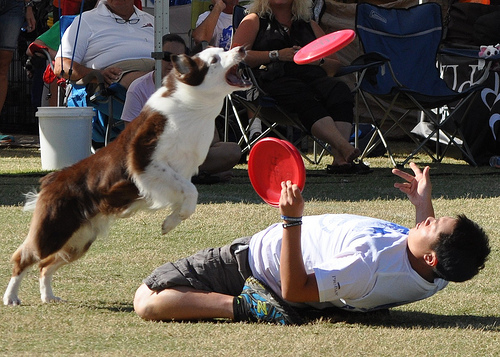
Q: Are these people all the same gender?
A: No, they are both male and female.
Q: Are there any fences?
A: No, there are no fences.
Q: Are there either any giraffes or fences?
A: No, there are no fences or giraffes.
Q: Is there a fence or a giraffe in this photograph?
A: No, there are no fences or giraffes.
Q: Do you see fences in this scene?
A: No, there are no fences.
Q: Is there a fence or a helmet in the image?
A: No, there are no fences or helmets.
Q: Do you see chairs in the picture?
A: Yes, there is a chair.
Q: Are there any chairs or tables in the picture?
A: Yes, there is a chair.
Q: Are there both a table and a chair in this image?
A: No, there is a chair but no tables.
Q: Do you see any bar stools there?
A: No, there are no bar stools.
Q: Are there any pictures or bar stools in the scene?
A: No, there are no bar stools or pictures.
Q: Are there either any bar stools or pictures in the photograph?
A: No, there are no bar stools or pictures.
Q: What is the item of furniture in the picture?
A: The piece of furniture is a chair.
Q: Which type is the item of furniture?
A: The piece of furniture is a chair.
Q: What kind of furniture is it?
A: The piece of furniture is a chair.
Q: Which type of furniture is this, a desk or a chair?
A: That is a chair.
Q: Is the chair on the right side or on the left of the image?
A: The chair is on the right of the image.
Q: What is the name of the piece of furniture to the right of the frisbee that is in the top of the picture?
A: The piece of furniture is a chair.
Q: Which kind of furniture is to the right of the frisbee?
A: The piece of furniture is a chair.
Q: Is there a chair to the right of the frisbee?
A: Yes, there is a chair to the right of the frisbee.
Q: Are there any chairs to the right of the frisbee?
A: Yes, there is a chair to the right of the frisbee.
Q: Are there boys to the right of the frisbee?
A: No, there is a chair to the right of the frisbee.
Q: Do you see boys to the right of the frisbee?
A: No, there is a chair to the right of the frisbee.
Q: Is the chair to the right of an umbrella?
A: No, the chair is to the right of a frisbee.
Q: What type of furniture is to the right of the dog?
A: The piece of furniture is a chair.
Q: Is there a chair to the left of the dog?
A: No, the chair is to the right of the dog.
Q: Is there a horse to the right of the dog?
A: No, there is a chair to the right of the dog.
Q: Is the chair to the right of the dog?
A: Yes, the chair is to the right of the dog.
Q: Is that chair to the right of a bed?
A: No, the chair is to the right of the dog.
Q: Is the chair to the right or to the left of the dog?
A: The chair is to the right of the dog.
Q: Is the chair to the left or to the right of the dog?
A: The chair is to the right of the dog.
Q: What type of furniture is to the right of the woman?
A: The piece of furniture is a chair.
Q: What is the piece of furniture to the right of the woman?
A: The piece of furniture is a chair.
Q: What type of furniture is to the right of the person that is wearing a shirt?
A: The piece of furniture is a chair.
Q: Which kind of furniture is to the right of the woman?
A: The piece of furniture is a chair.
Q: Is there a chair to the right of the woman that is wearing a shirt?
A: Yes, there is a chair to the right of the woman.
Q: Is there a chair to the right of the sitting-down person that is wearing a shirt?
A: Yes, there is a chair to the right of the woman.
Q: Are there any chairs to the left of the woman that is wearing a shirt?
A: No, the chair is to the right of the woman.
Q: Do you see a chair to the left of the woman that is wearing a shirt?
A: No, the chair is to the right of the woman.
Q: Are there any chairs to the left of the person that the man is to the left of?
A: No, the chair is to the right of the woman.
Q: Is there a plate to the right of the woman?
A: No, there is a chair to the right of the woman.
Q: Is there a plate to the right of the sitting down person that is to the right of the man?
A: No, there is a chair to the right of the woman.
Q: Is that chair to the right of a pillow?
A: No, the chair is to the right of the woman.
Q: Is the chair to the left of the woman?
A: No, the chair is to the right of the woman.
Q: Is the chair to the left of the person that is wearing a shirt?
A: No, the chair is to the right of the woman.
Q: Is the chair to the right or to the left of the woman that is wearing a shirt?
A: The chair is to the right of the woman.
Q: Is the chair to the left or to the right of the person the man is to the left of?
A: The chair is to the right of the woman.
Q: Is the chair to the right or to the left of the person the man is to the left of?
A: The chair is to the right of the woman.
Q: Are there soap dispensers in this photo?
A: No, there are no soap dispensers.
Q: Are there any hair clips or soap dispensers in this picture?
A: No, there are no soap dispensers or hair clips.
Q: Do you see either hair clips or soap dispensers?
A: No, there are no soap dispensers or hair clips.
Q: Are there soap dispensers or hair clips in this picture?
A: No, there are no soap dispensers or hair clips.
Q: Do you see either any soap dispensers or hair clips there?
A: No, there are no soap dispensers or hair clips.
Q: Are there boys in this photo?
A: No, there are no boys.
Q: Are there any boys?
A: No, there are no boys.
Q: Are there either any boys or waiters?
A: No, there are no boys or waiters.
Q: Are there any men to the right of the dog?
A: Yes, there is a man to the right of the dog.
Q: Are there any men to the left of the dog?
A: No, the man is to the right of the dog.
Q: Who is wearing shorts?
A: The man is wearing shorts.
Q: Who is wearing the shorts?
A: The man is wearing shorts.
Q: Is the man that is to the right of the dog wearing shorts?
A: Yes, the man is wearing shorts.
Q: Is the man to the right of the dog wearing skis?
A: No, the man is wearing shorts.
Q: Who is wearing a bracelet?
A: The man is wearing a bracelet.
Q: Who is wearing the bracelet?
A: The man is wearing a bracelet.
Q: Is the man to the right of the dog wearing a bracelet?
A: Yes, the man is wearing a bracelet.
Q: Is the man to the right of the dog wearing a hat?
A: No, the man is wearing a bracelet.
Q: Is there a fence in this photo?
A: No, there are no fences.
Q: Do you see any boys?
A: No, there are no boys.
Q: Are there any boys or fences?
A: No, there are no boys or fences.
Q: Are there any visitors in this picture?
A: No, there are no visitors.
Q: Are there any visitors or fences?
A: No, there are no visitors or fences.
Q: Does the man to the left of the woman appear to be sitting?
A: Yes, the man is sitting.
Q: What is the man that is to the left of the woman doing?
A: The man is sitting.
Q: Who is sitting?
A: The man is sitting.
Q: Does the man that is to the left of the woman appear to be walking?
A: No, the man is sitting.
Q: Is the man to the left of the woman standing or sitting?
A: The man is sitting.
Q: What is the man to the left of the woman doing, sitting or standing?
A: The man is sitting.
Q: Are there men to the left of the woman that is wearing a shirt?
A: Yes, there is a man to the left of the woman.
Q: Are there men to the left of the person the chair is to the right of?
A: Yes, there is a man to the left of the woman.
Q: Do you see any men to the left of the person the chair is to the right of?
A: Yes, there is a man to the left of the woman.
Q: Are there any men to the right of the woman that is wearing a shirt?
A: No, the man is to the left of the woman.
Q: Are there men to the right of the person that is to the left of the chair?
A: No, the man is to the left of the woman.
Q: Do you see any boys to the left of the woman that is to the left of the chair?
A: No, there is a man to the left of the woman.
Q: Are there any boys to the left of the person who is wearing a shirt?
A: No, there is a man to the left of the woman.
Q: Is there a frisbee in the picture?
A: Yes, there is a frisbee.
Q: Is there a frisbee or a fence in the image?
A: Yes, there is a frisbee.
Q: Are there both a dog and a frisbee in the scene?
A: Yes, there are both a frisbee and a dog.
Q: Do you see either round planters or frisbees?
A: Yes, there is a round frisbee.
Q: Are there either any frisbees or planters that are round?
A: Yes, the frisbee is round.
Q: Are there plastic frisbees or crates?
A: Yes, there is a plastic frisbee.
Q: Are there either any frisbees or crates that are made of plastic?
A: Yes, the frisbee is made of plastic.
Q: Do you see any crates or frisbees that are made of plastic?
A: Yes, the frisbee is made of plastic.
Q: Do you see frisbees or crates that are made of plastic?
A: Yes, the frisbee is made of plastic.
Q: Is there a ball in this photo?
A: No, there are no balls.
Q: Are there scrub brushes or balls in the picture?
A: No, there are no balls or scrub brushes.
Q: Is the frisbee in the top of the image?
A: Yes, the frisbee is in the top of the image.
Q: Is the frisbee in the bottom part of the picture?
A: No, the frisbee is in the top of the image.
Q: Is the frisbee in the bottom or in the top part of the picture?
A: The frisbee is in the top of the image.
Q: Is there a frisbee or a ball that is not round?
A: No, there is a frisbee but it is round.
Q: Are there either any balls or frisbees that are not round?
A: No, there is a frisbee but it is round.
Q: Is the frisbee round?
A: Yes, the frisbee is round.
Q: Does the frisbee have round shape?
A: Yes, the frisbee is round.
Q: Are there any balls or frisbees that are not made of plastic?
A: No, there is a frisbee but it is made of plastic.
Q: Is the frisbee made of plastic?
A: Yes, the frisbee is made of plastic.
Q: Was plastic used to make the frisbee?
A: Yes, the frisbee is made of plastic.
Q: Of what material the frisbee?
A: The frisbee is made of plastic.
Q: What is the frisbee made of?
A: The frisbee is made of plastic.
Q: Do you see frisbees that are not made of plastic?
A: No, there is a frisbee but it is made of plastic.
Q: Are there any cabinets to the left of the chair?
A: No, there is a frisbee to the left of the chair.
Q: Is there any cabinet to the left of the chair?
A: No, there is a frisbee to the left of the chair.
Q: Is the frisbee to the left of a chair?
A: Yes, the frisbee is to the left of a chair.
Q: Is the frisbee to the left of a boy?
A: No, the frisbee is to the left of a chair.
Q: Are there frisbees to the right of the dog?
A: Yes, there is a frisbee to the right of the dog.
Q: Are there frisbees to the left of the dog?
A: No, the frisbee is to the right of the dog.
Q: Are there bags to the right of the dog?
A: No, there is a frisbee to the right of the dog.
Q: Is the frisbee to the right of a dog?
A: Yes, the frisbee is to the right of a dog.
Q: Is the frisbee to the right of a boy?
A: No, the frisbee is to the right of a dog.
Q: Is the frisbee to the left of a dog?
A: No, the frisbee is to the right of a dog.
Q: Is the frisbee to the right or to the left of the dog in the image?
A: The frisbee is to the right of the dog.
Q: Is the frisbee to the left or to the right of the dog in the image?
A: The frisbee is to the right of the dog.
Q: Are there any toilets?
A: No, there are no toilets.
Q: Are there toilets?
A: No, there are no toilets.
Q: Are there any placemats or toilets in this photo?
A: No, there are no toilets or placemats.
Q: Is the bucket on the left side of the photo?
A: Yes, the bucket is on the left of the image.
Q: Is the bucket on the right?
A: No, the bucket is on the left of the image.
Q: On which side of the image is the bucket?
A: The bucket is on the left of the image.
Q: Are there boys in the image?
A: No, there are no boys.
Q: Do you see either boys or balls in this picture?
A: No, there are no boys or balls.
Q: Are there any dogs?
A: Yes, there is a dog.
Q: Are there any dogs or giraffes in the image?
A: Yes, there is a dog.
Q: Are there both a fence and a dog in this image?
A: No, there is a dog but no fences.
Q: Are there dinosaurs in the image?
A: No, there are no dinosaurs.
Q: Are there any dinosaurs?
A: No, there are no dinosaurs.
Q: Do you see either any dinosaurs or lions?
A: No, there are no dinosaurs or lions.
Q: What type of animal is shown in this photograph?
A: The animal is a dog.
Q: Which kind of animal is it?
A: The animal is a dog.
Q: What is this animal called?
A: That is a dog.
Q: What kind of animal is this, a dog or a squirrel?
A: That is a dog.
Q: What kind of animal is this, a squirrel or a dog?
A: That is a dog.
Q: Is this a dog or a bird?
A: This is a dog.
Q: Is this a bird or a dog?
A: This is a dog.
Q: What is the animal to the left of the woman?
A: The animal is a dog.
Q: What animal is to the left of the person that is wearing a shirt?
A: The animal is a dog.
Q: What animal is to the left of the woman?
A: The animal is a dog.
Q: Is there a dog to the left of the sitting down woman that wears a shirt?
A: Yes, there is a dog to the left of the woman.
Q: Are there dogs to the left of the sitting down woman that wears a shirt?
A: Yes, there is a dog to the left of the woman.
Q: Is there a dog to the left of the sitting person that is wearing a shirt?
A: Yes, there is a dog to the left of the woman.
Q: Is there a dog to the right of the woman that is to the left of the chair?
A: No, the dog is to the left of the woman.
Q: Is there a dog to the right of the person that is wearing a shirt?
A: No, the dog is to the left of the woman.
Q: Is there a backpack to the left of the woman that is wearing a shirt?
A: No, there is a dog to the left of the woman.